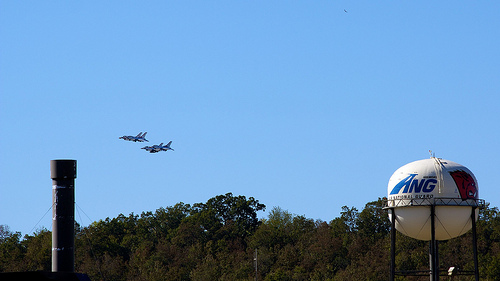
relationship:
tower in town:
[47, 160, 88, 278] [25, 152, 499, 280]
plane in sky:
[140, 136, 180, 165] [2, 1, 500, 241]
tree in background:
[0, 197, 500, 273] [18, 139, 499, 266]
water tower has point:
[382, 150, 487, 280] [427, 151, 443, 161]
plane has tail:
[140, 136, 180, 165] [163, 137, 173, 153]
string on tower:
[78, 199, 98, 231] [47, 160, 88, 278]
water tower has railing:
[382, 150, 487, 280] [382, 196, 487, 213]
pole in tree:
[250, 240, 266, 280] [0, 197, 500, 273]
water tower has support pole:
[382, 150, 487, 280] [384, 209, 403, 280]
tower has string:
[47, 160, 88, 278] [78, 199, 98, 231]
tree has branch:
[0, 197, 500, 273] [344, 202, 360, 230]